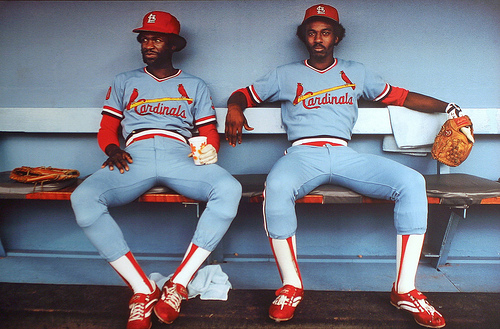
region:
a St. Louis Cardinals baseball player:
[223, 4, 478, 322]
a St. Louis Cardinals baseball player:
[67, 8, 244, 325]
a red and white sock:
[107, 251, 150, 293]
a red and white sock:
[167, 243, 211, 288]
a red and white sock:
[268, 234, 303, 288]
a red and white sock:
[394, 230, 426, 291]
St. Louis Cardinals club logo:
[291, 68, 360, 112]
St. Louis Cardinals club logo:
[123, 85, 195, 120]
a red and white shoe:
[125, 278, 158, 326]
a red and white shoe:
[154, 274, 189, 324]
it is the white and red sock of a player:
[265, 240, 307, 282]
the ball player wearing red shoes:
[273, 287, 299, 319]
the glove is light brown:
[439, 114, 474, 165]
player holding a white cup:
[188, 135, 211, 165]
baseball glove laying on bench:
[17, 158, 83, 187]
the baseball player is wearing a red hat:
[132, 10, 181, 35]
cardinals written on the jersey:
[292, 67, 355, 119]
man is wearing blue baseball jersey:
[275, 66, 362, 137]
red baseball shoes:
[126, 278, 199, 324]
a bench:
[13, 153, 488, 245]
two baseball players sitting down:
[45, 5, 472, 257]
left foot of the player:
[385, 266, 450, 323]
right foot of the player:
[248, 264, 323, 326]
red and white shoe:
[258, 282, 310, 322]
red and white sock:
[266, 230, 306, 272]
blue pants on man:
[262, 161, 419, 221]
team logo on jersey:
[285, 68, 365, 128]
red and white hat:
[128, 4, 186, 41]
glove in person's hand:
[426, 87, 488, 173]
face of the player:
[296, 19, 342, 59]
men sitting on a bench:
[43, 1, 484, 327]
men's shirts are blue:
[85, 46, 422, 154]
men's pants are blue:
[47, 126, 440, 273]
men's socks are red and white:
[82, 231, 434, 300]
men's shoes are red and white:
[95, 284, 479, 327]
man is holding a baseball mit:
[413, 84, 483, 180]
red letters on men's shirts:
[91, 84, 387, 131]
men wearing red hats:
[96, 3, 372, 33]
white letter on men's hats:
[130, 0, 341, 25]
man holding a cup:
[167, 115, 224, 177]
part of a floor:
[347, 291, 375, 320]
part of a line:
[291, 255, 303, 295]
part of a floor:
[317, 275, 351, 313]